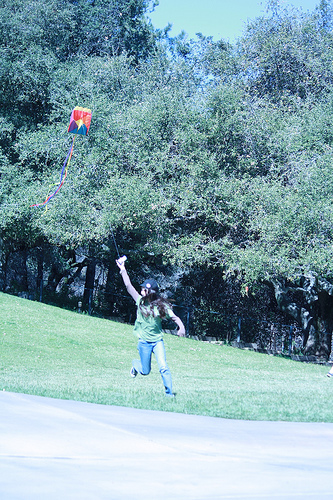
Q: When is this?
A: Daytime.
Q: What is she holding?
A: A string.